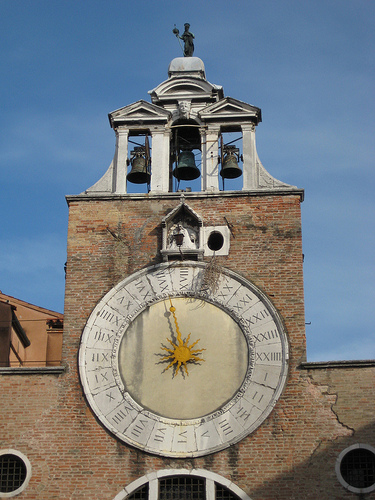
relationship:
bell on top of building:
[124, 146, 152, 184] [3, 20, 375, 499]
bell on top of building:
[173, 145, 199, 179] [3, 20, 375, 499]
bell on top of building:
[220, 144, 244, 176] [3, 20, 375, 499]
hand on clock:
[163, 287, 205, 379] [75, 259, 292, 459]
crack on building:
[307, 369, 355, 464] [3, 20, 375, 499]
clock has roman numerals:
[75, 259, 292, 459] [86, 267, 284, 445]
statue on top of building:
[170, 19, 196, 55] [3, 20, 375, 499]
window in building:
[334, 445, 373, 495] [3, 20, 375, 499]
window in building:
[0, 448, 34, 498] [3, 20, 375, 499]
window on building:
[334, 445, 373, 495] [3, 20, 375, 499]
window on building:
[0, 448, 34, 498] [3, 20, 375, 499]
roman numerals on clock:
[86, 267, 284, 445] [75, 259, 292, 459]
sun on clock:
[155, 330, 207, 380] [75, 259, 292, 459]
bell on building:
[124, 146, 152, 184] [3, 20, 375, 499]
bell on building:
[173, 145, 199, 179] [3, 20, 375, 499]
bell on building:
[220, 144, 244, 176] [3, 20, 375, 499]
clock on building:
[75, 259, 292, 459] [3, 20, 375, 499]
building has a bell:
[3, 20, 375, 499] [124, 146, 152, 184]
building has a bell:
[3, 20, 375, 499] [173, 145, 199, 179]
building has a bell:
[3, 20, 375, 499] [220, 144, 244, 176]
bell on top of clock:
[124, 146, 152, 184] [75, 259, 292, 459]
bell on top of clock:
[173, 145, 199, 179] [75, 259, 292, 459]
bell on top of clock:
[220, 144, 244, 176] [75, 259, 292, 459]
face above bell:
[179, 98, 193, 117] [173, 145, 199, 179]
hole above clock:
[206, 228, 223, 249] [75, 259, 292, 459]